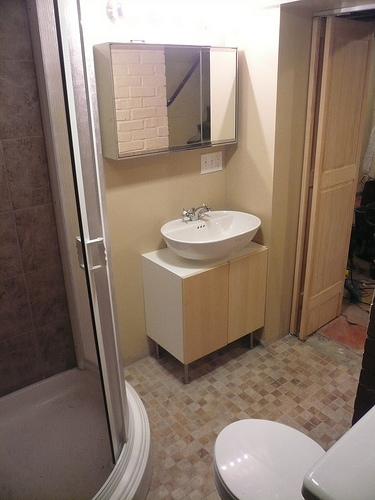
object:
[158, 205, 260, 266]
sink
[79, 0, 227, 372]
wall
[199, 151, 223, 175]
outlets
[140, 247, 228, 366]
cabinet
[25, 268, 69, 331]
tiles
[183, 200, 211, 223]
faucet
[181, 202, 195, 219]
handle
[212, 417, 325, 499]
toilet seat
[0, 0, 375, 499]
bathroom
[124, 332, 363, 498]
bathroom floor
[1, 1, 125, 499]
door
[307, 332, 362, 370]
doorstep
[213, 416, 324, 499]
toilet cover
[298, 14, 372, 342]
door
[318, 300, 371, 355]
rug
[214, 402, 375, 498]
toilet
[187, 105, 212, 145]
staircase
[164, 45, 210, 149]
mirror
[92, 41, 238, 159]
medicine cabinet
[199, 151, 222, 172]
light switch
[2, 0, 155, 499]
shower area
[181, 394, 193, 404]
tile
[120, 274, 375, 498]
floor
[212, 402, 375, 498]
commode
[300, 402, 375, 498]
tank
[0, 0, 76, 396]
wall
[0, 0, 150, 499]
shower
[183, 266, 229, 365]
door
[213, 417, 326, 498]
toilet top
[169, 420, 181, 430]
tile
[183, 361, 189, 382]
leg